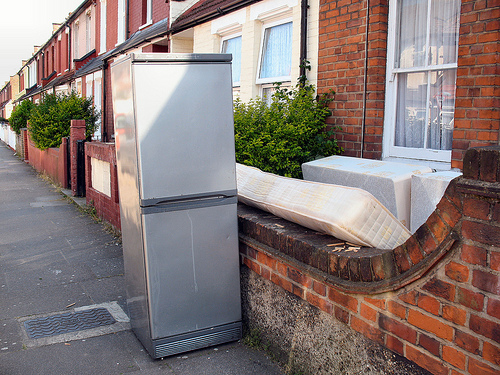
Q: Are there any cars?
A: No, there are no cars.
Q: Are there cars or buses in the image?
A: No, there are no cars or buses.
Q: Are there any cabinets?
A: No, there are no cabinets.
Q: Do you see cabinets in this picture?
A: No, there are no cabinets.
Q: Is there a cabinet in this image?
A: No, there are no cabinets.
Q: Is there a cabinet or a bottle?
A: No, there are no cabinets or bottles.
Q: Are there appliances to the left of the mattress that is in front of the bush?
A: Yes, there is an appliance to the left of the mattress.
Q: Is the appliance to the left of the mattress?
A: Yes, the appliance is to the left of the mattress.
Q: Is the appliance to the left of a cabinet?
A: No, the appliance is to the left of the mattress.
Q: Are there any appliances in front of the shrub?
A: Yes, there is an appliance in front of the shrub.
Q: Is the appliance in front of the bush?
A: Yes, the appliance is in front of the bush.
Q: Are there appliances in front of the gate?
A: Yes, there is an appliance in front of the gate.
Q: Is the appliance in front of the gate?
A: Yes, the appliance is in front of the gate.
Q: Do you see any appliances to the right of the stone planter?
A: Yes, there is an appliance to the right of the planter.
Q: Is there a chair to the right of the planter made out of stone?
A: No, there is an appliance to the right of the planter.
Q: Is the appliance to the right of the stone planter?
A: Yes, the appliance is to the right of the planter.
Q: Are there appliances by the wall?
A: Yes, there is an appliance by the wall.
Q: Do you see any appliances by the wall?
A: Yes, there is an appliance by the wall.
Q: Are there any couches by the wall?
A: No, there is an appliance by the wall.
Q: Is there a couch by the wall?
A: No, there is an appliance by the wall.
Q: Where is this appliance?
A: The appliance is on the sidewalk.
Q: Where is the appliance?
A: The appliance is on the sidewalk.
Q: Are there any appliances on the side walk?
A: Yes, there is an appliance on the side walk.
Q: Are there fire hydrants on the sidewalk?
A: No, there is an appliance on the sidewalk.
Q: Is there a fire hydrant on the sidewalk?
A: No, there is an appliance on the sidewalk.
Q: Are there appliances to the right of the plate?
A: Yes, there is an appliance to the right of the plate.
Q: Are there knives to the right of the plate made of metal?
A: No, there is an appliance to the right of the plate.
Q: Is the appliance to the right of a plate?
A: Yes, the appliance is to the right of a plate.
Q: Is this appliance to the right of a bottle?
A: No, the appliance is to the right of a plate.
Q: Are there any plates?
A: Yes, there is a plate.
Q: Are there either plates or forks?
A: Yes, there is a plate.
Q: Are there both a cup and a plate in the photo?
A: No, there is a plate but no cups.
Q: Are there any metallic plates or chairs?
A: Yes, there is a metal plate.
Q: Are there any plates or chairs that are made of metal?
A: Yes, the plate is made of metal.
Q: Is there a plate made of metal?
A: Yes, there is a plate that is made of metal.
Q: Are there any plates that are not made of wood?
A: Yes, there is a plate that is made of metal.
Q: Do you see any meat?
A: No, there is no meat.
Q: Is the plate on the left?
A: Yes, the plate is on the left of the image.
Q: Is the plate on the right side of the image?
A: No, the plate is on the left of the image.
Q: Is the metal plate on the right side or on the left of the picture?
A: The plate is on the left of the image.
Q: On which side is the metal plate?
A: The plate is on the left of the image.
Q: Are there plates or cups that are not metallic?
A: No, there is a plate but it is metallic.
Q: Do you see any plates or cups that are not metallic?
A: No, there is a plate but it is metallic.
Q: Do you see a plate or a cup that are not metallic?
A: No, there is a plate but it is metallic.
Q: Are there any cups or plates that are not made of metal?
A: No, there is a plate but it is made of metal.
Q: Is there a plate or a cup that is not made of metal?
A: No, there is a plate but it is made of metal.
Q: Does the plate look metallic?
A: Yes, the plate is metallic.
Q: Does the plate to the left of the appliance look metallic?
A: Yes, the plate is metallic.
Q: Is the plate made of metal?
A: Yes, the plate is made of metal.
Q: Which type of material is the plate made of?
A: The plate is made of metal.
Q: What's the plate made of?
A: The plate is made of metal.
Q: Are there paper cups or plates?
A: No, there is a plate but it is metallic.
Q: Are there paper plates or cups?
A: No, there is a plate but it is metallic.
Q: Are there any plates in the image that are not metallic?
A: No, there is a plate but it is metallic.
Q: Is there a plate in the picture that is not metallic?
A: No, there is a plate but it is metallic.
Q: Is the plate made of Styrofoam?
A: No, the plate is made of metal.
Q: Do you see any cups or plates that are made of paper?
A: No, there is a plate but it is made of metal.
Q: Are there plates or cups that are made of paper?
A: No, there is a plate but it is made of metal.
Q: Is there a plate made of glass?
A: No, there is a plate but it is made of metal.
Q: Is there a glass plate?
A: No, there is a plate but it is made of metal.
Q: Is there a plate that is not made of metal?
A: No, there is a plate but it is made of metal.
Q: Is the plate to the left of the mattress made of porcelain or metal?
A: The plate is made of metal.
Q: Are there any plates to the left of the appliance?
A: Yes, there is a plate to the left of the appliance.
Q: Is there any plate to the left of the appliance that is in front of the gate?
A: Yes, there is a plate to the left of the appliance.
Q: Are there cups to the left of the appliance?
A: No, there is a plate to the left of the appliance.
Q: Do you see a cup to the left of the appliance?
A: No, there is a plate to the left of the appliance.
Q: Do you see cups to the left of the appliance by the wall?
A: No, there is a plate to the left of the appliance.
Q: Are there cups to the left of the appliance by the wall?
A: No, there is a plate to the left of the appliance.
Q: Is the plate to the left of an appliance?
A: Yes, the plate is to the left of an appliance.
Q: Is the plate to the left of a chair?
A: No, the plate is to the left of an appliance.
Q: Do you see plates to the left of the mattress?
A: Yes, there is a plate to the left of the mattress.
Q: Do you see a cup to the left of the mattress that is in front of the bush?
A: No, there is a plate to the left of the mattress.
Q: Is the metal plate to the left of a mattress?
A: Yes, the plate is to the left of a mattress.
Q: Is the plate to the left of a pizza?
A: No, the plate is to the left of a mattress.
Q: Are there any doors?
A: Yes, there is a door.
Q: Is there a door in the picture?
A: Yes, there is a door.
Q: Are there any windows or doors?
A: Yes, there is a door.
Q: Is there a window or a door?
A: Yes, there is a door.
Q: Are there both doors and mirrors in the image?
A: No, there is a door but no mirrors.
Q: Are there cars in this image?
A: No, there are no cars.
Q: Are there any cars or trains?
A: No, there are no cars or trains.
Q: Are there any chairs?
A: No, there are no chairs.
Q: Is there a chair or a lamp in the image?
A: No, there are no chairs or lamps.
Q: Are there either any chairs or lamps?
A: No, there are no chairs or lamps.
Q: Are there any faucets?
A: No, there are no faucets.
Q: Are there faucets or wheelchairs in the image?
A: No, there are no faucets or wheelchairs.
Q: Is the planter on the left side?
A: Yes, the planter is on the left of the image.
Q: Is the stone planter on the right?
A: No, the planter is on the left of the image.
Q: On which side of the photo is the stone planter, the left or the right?
A: The planter is on the left of the image.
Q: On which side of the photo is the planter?
A: The planter is on the left of the image.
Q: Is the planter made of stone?
A: Yes, the planter is made of stone.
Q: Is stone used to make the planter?
A: Yes, the planter is made of stone.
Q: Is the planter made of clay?
A: No, the planter is made of stone.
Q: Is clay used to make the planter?
A: No, the planter is made of stone.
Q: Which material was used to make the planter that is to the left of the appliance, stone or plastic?
A: The planter is made of stone.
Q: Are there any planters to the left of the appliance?
A: Yes, there is a planter to the left of the appliance.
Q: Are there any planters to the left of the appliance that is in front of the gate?
A: Yes, there is a planter to the left of the appliance.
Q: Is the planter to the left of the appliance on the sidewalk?
A: Yes, the planter is to the left of the appliance.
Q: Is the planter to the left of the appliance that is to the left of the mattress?
A: Yes, the planter is to the left of the appliance.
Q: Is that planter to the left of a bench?
A: No, the planter is to the left of the appliance.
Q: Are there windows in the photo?
A: Yes, there are windows.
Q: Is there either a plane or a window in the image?
A: Yes, there are windows.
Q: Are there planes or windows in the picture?
A: Yes, there are windows.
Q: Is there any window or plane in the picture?
A: Yes, there are windows.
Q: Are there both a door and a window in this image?
A: Yes, there are both a window and a door.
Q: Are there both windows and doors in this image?
A: Yes, there are both windows and a door.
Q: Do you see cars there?
A: No, there are no cars.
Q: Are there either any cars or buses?
A: No, there are no cars or buses.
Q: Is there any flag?
A: No, there are no flags.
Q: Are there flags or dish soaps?
A: No, there are no flags or dish soaps.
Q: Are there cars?
A: No, there are no cars.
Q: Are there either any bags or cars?
A: No, there are no cars or bags.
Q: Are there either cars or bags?
A: No, there are no cars or bags.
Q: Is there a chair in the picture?
A: No, there are no chairs.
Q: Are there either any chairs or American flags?
A: No, there are no chairs or American flags.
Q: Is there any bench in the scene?
A: No, there are no benches.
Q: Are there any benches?
A: No, there are no benches.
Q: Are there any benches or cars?
A: No, there are no benches or cars.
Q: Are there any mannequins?
A: No, there are no mannequins.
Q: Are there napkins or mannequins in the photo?
A: No, there are no mannequins or napkins.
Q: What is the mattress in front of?
A: The mattress is in front of the shrub.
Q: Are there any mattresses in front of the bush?
A: Yes, there is a mattress in front of the bush.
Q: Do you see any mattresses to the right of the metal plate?
A: Yes, there is a mattress to the right of the plate.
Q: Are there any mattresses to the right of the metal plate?
A: Yes, there is a mattress to the right of the plate.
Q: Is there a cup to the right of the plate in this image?
A: No, there is a mattress to the right of the plate.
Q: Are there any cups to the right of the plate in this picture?
A: No, there is a mattress to the right of the plate.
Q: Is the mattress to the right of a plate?
A: Yes, the mattress is to the right of a plate.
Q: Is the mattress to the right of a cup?
A: No, the mattress is to the right of a plate.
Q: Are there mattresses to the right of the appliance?
A: Yes, there is a mattress to the right of the appliance.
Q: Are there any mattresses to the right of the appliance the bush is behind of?
A: Yes, there is a mattress to the right of the appliance.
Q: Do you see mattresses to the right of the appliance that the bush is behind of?
A: Yes, there is a mattress to the right of the appliance.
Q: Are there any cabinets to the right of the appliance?
A: No, there is a mattress to the right of the appliance.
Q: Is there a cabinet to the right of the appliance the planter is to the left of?
A: No, there is a mattress to the right of the appliance.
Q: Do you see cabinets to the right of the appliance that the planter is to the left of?
A: No, there is a mattress to the right of the appliance.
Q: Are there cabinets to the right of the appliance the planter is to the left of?
A: No, there is a mattress to the right of the appliance.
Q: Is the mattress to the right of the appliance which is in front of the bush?
A: Yes, the mattress is to the right of the appliance.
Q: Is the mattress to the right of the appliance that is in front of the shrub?
A: Yes, the mattress is to the right of the appliance.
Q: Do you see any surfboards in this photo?
A: No, there are no surfboards.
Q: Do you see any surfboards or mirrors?
A: No, there are no surfboards or mirrors.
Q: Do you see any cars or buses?
A: No, there are no cars or buses.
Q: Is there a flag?
A: No, there are no flags.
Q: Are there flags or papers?
A: No, there are no flags or papers.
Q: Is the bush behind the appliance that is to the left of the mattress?
A: Yes, the bush is behind the appliance.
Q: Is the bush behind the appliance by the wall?
A: Yes, the bush is behind the appliance.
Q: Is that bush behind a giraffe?
A: No, the bush is behind the appliance.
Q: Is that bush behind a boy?
A: No, the bush is behind the mattress.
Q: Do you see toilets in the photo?
A: No, there are no toilets.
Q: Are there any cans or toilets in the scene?
A: No, there are no toilets or cans.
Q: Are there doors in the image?
A: Yes, there is a door.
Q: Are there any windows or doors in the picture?
A: Yes, there is a door.